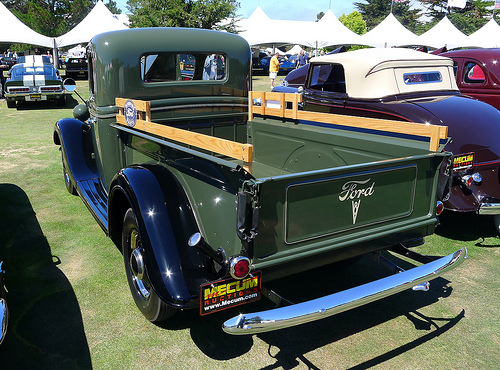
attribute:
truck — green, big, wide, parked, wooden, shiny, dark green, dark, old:
[46, 17, 467, 328]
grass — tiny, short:
[3, 102, 492, 362]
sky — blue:
[16, 2, 492, 40]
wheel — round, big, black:
[116, 202, 181, 329]